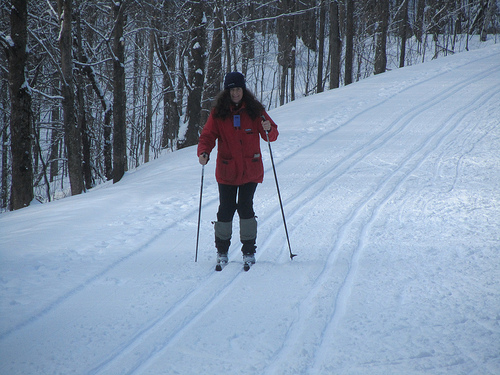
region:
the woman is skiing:
[141, 58, 338, 305]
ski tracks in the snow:
[293, 94, 405, 204]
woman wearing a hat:
[174, 52, 269, 125]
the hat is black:
[194, 67, 255, 123]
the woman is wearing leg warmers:
[187, 203, 267, 267]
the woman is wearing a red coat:
[176, 54, 283, 204]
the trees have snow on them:
[15, 6, 170, 185]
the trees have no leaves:
[15, 0, 173, 120]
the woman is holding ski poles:
[110, 117, 321, 276]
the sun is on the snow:
[322, 135, 466, 250]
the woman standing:
[190, 69, 299, 274]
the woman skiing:
[195, 71, 294, 274]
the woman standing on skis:
[190, 66, 295, 273]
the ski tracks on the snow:
[306, 77, 436, 190]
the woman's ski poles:
[189, 118, 296, 262]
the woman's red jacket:
[196, 99, 279, 184]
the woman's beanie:
[222, 68, 244, 85]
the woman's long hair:
[213, 88, 265, 117]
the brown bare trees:
[15, 10, 384, 147]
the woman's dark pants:
[210, 175, 267, 260]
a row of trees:
[33, 11, 468, 84]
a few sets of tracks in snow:
[103, 287, 349, 370]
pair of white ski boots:
[188, 247, 261, 273]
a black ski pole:
[254, 115, 312, 272]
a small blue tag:
[229, 110, 248, 137]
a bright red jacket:
[180, 92, 295, 203]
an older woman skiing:
[179, 54, 303, 274]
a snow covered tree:
[153, 4, 216, 149]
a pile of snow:
[379, 251, 486, 357]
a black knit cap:
[206, 56, 258, 108]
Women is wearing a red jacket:
[188, 53, 304, 210]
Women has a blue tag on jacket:
[201, 63, 276, 150]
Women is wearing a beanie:
[180, 64, 310, 154]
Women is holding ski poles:
[184, 65, 322, 285]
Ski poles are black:
[175, 111, 310, 288]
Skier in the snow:
[178, 56, 322, 293]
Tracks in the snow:
[113, 46, 490, 368]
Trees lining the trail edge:
[33, 6, 477, 205]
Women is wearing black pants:
[188, 72, 302, 270]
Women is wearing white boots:
[171, 63, 336, 305]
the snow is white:
[143, 280, 241, 367]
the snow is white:
[308, 291, 387, 369]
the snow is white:
[265, 272, 323, 365]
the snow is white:
[279, 245, 361, 373]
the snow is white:
[342, 304, 382, 365]